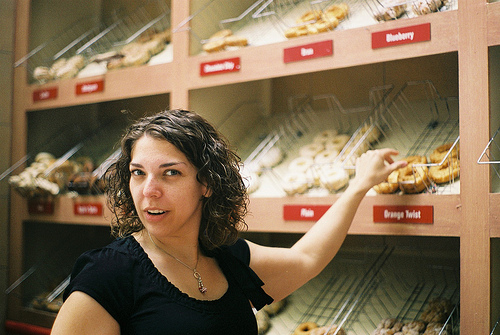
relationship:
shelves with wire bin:
[15, 5, 471, 329] [254, 97, 384, 202]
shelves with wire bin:
[15, 5, 471, 329] [350, 79, 461, 199]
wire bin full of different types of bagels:
[350, 79, 461, 199] [275, 109, 463, 193]